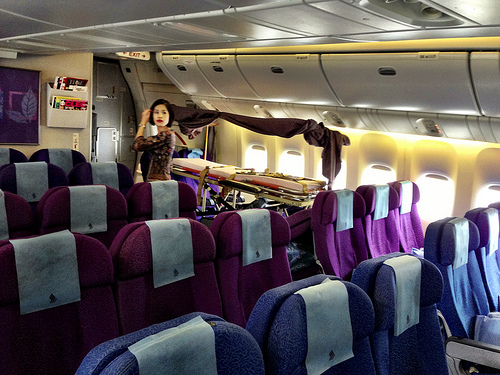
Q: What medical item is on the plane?
A: A stretcher.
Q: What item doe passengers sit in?
A: A seat.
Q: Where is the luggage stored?
A: Overhead compartments.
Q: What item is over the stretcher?
A: Curtains.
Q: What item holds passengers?
A: Seats.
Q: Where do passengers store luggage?
A: Overhead bins.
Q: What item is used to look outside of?
A: A window.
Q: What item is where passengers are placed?
A: Seats.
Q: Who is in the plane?
A: A woman.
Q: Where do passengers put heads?
A: The headrest.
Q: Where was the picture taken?
A: In an airplane.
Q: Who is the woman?
A: A stewardess.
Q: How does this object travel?
A: By air.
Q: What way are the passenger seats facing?
A: To the right.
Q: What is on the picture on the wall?
A: Leaves.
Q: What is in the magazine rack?
A: Magazines.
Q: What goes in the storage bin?
A: Luggage.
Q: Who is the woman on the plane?
A: Flight attendant.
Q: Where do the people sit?
A: Chairs.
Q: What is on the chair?
A: Seat cover.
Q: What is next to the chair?
A: Window.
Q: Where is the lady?
A: On a plane.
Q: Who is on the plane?
A: The lady.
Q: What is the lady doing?
A: Standing.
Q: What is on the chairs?
A: Towels.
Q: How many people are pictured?
A: One.